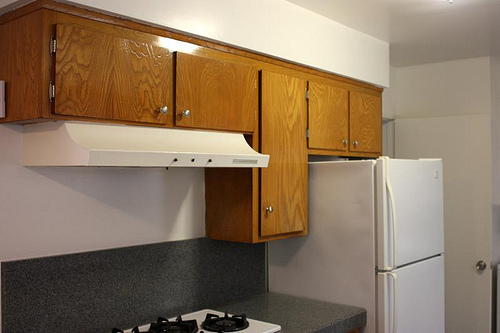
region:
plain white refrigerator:
[315, 156, 462, 331]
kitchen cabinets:
[20, 5, 400, 245]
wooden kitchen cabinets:
[5, 5, 395, 250]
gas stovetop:
[105, 305, 271, 330]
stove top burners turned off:
[106, 305, 266, 325]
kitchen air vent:
[20, 116, 255, 171]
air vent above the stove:
[15, 115, 265, 175]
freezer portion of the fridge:
[301, 155, 457, 265]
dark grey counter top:
[220, 236, 361, 321]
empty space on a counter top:
[212, 250, 357, 323]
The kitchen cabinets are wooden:
[3, 1, 382, 243]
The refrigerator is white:
[263, 153, 458, 330]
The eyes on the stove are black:
[116, 309, 256, 331]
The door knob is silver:
[471, 257, 488, 275]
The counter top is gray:
[1, 238, 368, 331]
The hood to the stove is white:
[14, 116, 271, 171]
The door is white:
[392, 113, 499, 331]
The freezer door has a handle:
[373, 157, 446, 269]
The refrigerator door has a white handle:
[373, 250, 463, 331]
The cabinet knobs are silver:
[260, 200, 277, 220]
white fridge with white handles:
[272, 151, 452, 330]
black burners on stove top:
[116, 304, 272, 332]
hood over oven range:
[12, 120, 263, 174]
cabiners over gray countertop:
[9, 5, 388, 240]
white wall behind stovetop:
[5, 133, 210, 247]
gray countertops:
[12, 244, 360, 332]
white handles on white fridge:
[383, 185, 405, 326]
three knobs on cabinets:
[152, 100, 278, 217]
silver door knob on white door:
[475, 257, 487, 274]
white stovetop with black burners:
[106, 305, 285, 332]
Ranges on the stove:
[110, 309, 254, 331]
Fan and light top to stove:
[20, 116, 277, 186]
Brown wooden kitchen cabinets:
[0, 2, 390, 258]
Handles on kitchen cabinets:
[149, 98, 201, 123]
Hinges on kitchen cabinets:
[45, 33, 61, 101]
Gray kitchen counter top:
[205, 281, 372, 331]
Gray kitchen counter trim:
[0, 227, 279, 332]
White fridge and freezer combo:
[262, 152, 454, 330]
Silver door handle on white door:
[464, 256, 491, 279]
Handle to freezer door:
[381, 154, 399, 271]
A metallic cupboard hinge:
[48, 32, 58, 57]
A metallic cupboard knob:
[158, 102, 169, 113]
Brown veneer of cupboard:
[77, 31, 157, 111]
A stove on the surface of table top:
[122, 301, 274, 328]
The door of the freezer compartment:
[375, 150, 445, 265]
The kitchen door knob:
[475, 255, 485, 270]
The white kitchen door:
[450, 115, 485, 251]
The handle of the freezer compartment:
[385, 175, 401, 265]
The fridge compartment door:
[379, 259, 446, 330]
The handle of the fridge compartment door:
[389, 270, 404, 331]